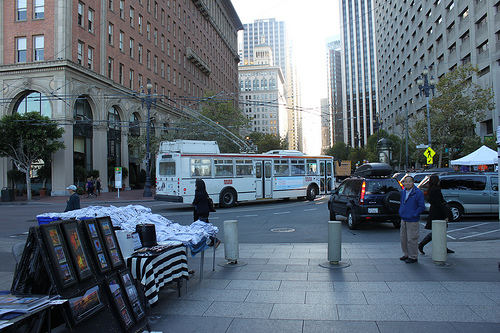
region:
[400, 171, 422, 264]
man in blue shirt looking down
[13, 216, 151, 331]
artwork on display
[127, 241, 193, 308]
black and white striped table cloth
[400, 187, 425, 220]
blue jacket on a man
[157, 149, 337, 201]
white city bus on the street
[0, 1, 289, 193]
tall buildings in the background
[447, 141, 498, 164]
white canopy behind cars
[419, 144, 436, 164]
pedestrian walk sign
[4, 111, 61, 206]
medium size tree growing next to bulding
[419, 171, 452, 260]
lady in black walking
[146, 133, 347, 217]
a white city bus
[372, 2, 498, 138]
the facade of a building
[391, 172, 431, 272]
an Asian man wearing a blue jacket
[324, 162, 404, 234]
a car on a busy city street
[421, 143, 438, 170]
a yellow pedestrian sign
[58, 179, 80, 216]
a man wearing a baseball cap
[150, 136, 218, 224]
a woman standing in front of a bus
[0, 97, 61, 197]
a tree on a city street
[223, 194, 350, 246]
a city street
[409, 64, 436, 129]
a lamp post on a city street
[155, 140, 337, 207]
a white public service bus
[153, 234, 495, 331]
a brick paved city sidewalk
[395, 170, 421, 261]
a man standing on sidewalk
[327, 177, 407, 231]
a blue SUV in street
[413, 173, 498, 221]
a parked minivan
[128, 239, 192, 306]
a black and white striped tablecloth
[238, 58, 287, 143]
a tall building in distance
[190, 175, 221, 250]
a pedestrian on sidewalk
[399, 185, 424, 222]
a man's blue jacket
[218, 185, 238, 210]
a bus rear tire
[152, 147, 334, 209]
white bus on road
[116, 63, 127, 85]
window on side of building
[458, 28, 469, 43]
window on side of building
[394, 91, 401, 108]
window on side of building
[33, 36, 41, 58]
window on side of building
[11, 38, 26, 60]
window on side of building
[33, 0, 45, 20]
window on side of building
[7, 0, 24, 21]
window on side of building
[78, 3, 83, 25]
window on side of building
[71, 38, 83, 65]
window on side of building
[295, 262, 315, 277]
part of a floor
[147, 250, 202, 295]
part of a cloth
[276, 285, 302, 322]
part of a floor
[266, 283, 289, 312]
part of a floor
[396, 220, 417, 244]
part of a trouser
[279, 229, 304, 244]
edge of a road